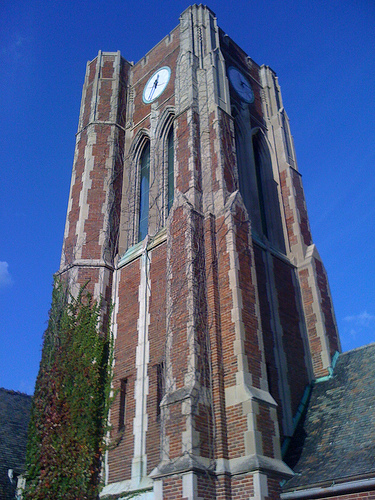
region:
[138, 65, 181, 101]
Clock on a building.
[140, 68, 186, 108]
Blue around the clock.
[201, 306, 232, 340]
The building is brick.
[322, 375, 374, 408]
Brick is visible through the shingles.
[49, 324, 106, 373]
Plant growing on the building.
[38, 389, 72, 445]
Red in the plant.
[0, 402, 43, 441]
The shingles are black.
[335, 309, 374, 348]
Thin cloud in the sky.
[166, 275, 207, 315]
Brown vine growing up the tree.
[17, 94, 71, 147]
The sky is dark blue.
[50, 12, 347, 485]
tall brick and stone tower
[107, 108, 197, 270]
tall arched windows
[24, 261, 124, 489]
green vines growing up a building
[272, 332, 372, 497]
dark grey shingled roof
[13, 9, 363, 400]
cloudless deep blue sky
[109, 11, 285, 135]
pair of big clocks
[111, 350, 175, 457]
small rectangular windows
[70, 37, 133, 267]
brick and stone mix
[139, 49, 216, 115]
white clock with black hands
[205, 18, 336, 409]
shadow over tower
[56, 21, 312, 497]
a tall brick building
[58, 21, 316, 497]
a tall old building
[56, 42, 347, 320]
a brick building with a clock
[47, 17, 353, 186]
a tall building with a clock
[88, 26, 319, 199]
a building with two clocks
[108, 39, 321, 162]
a building with two clocks outside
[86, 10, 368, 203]
a building with two outside clocks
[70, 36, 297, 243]
a brick building with two clocks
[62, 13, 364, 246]
an old building with two clocks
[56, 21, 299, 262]
brick building with vines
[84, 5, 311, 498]
Tall four sided clock tower.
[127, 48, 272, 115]
Two clocks situated one corner.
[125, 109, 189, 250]
Double arched stain glass windows.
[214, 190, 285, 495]
Red brick encased gray cement.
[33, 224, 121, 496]
Foliage creeps side building.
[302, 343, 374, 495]
Attached dark slate roof.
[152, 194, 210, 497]
Sparse vine winding upward.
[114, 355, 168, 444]
Very thin windows or slots.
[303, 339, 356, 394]
Green grout recently added.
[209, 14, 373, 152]
Deep blue sky complements tower.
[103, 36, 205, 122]
a clock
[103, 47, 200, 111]
a clock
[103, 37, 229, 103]
a clock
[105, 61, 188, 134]
a clock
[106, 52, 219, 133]
a clock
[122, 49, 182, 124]
a clock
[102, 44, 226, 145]
a clock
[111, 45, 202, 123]
a clock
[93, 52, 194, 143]
a clock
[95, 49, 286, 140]
a clock